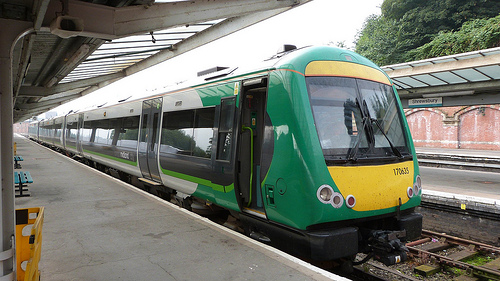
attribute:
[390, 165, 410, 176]
numbers — black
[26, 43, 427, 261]
train — green, yellow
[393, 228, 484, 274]
tracks — rusted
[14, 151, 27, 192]
benches — blue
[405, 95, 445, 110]
sign — green, white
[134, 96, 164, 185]
doors — gray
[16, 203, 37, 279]
moving crates — yellow, black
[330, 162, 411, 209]
section — yellow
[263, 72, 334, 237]
section — green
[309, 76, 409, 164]
windshield — large, clear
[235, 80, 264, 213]
door — open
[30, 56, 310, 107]
top section — gray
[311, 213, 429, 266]
front — black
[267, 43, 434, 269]
train — green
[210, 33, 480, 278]
train — green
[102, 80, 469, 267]
train — green, yellow, white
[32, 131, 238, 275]
platform — elevated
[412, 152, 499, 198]
platform — elevated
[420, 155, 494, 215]
platform — elevated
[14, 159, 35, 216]
wood bench — green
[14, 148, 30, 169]
wood bench — green